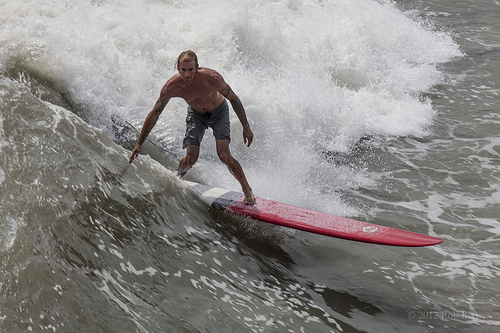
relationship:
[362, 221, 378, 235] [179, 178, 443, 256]
logo on surfboard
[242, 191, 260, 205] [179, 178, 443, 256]
feet on surfboard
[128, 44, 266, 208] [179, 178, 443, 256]
man standing on surfboard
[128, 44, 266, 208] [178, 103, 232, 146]
man wearing shorts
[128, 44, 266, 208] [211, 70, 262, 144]
man has arm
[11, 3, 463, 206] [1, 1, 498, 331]
wave in water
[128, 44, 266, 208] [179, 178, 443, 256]
man on surfboard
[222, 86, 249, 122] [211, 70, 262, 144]
tattoos on arm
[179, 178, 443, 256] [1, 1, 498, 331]
surfboard in water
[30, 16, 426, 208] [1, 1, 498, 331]
foam in water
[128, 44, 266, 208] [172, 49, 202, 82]
man has head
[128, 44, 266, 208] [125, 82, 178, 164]
man has arm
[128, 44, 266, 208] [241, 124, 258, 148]
man has hand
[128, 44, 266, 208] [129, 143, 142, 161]
man has hand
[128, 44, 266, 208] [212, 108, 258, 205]
man has leg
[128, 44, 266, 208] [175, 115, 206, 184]
man has leg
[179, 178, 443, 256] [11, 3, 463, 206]
surfboard touching wave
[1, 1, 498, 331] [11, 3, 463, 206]
water ahead of wave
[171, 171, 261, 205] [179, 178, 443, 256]
feet on surfboard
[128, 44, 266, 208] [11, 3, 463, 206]
man on wave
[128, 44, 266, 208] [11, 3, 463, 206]
man in wave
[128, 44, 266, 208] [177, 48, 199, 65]
man has hair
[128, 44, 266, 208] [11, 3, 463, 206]
man riding wave